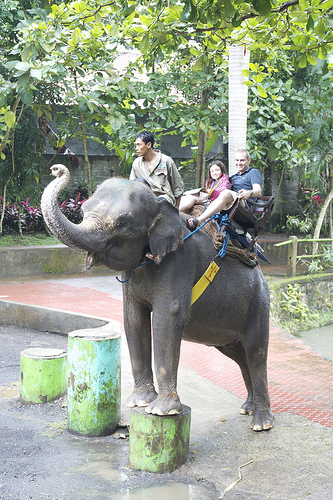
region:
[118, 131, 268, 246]
people on the back of the elephant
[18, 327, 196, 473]
three green posts for the elephant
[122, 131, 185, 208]
man driving the elephant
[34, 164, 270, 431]
gray elephant standing on a green post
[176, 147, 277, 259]
father and a daughter riding an elephant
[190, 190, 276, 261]
small wooden bench on the elephant's back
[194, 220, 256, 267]
folded blanket on the elephants back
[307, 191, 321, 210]
red flower growing in the trees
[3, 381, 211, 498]
puddles on the ground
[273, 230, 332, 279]
wooden rail behind the elephant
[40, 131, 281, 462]
Grey elephant carrying three people.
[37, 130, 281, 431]
Elephant with people on its back.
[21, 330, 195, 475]
Three faded green pillar.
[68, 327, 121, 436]
Tallest green pillar in the center.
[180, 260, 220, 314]
Thick yellow strap across elephant.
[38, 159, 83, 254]
Upturned trunk of elephant.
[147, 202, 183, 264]
Large ear of elephant.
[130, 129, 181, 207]
Dark haired man in brown shirt.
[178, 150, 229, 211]
Woman on elephant in pink top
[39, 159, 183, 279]
Head of elephant carrying people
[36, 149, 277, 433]
Two people sitting on an elephant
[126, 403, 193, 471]
an elephant standing on a stump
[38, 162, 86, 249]
an elephant's long trunk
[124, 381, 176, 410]
an elephant's front feet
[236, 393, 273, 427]
an elephant's hind feet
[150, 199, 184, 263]
the floppy ear of an elephant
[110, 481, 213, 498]
a puddle of mud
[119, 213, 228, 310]
a harness on an elephant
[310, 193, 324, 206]
a pretty pink flower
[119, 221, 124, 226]
the eye of an elephant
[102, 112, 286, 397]
people on a elephant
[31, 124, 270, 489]
elephant on a block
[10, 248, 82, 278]
a concerte wall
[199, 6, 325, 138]
a tree in the back ground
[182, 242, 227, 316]
a yellow strap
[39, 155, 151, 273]
a elephants trunk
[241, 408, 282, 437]
a elephant foot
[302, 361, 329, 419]
red tiles on the ground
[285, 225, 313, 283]
a brown fence post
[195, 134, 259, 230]
a man and child in a seat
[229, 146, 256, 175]
the man is smiling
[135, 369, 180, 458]
the elephant is standing on a stump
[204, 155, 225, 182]
the girl is smiling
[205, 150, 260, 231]
the two are sitting on a bench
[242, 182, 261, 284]
the bench is hooked to the elephant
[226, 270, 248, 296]
the elephant is gray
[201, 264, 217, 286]
the starp is yellow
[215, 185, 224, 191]
the coat is pink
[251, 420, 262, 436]
the toe nails are white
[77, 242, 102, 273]
the elephant has its mouth open